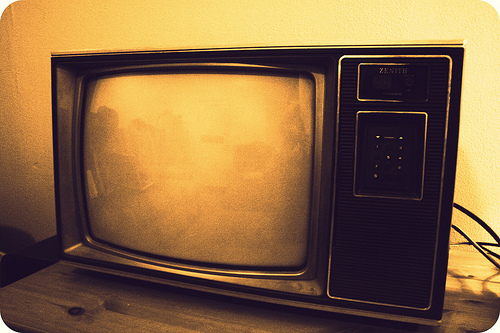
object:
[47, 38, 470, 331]
television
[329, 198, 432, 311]
speaker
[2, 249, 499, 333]
table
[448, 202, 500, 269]
cable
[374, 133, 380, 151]
button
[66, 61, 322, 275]
monitor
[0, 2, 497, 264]
wall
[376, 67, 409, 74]
word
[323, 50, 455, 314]
trim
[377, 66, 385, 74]
letters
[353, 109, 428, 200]
control panel